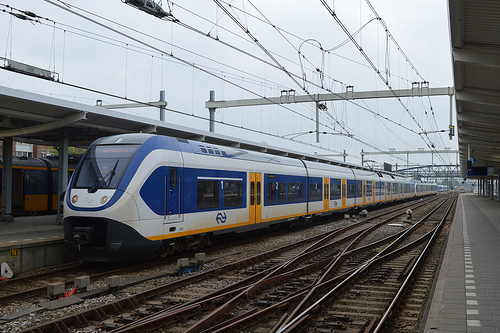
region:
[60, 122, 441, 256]
a long colorful train partked on the track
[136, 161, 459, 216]
the blue strip on the train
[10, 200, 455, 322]
the empty tracks next to the train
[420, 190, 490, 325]
the platform next to othe enpty track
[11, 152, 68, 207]
another colorful train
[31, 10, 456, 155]
assorted electrical equipment above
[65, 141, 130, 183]
the front window of the train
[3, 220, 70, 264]
another section of the platform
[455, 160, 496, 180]
a sign above the platform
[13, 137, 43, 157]
a building off in the background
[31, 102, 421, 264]
A train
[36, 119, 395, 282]
A blue, white and yellow train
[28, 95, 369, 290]
A train at a station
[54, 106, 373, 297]
A train on tracks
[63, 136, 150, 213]
The windshield of a train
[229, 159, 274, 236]
The doors of a train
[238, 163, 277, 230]
The yellow doors of a train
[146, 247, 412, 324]
train tracks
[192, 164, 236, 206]
A white number "1"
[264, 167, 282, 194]
A white number "2"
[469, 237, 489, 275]
part of a walkpath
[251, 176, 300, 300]
edge of a rail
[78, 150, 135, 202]
part of a window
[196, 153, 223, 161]
part of the upper edge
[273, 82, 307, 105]
part of a metal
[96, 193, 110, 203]
part of aheadlight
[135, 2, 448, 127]
A lot of wires above.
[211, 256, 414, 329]
Train tracks.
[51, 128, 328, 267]
The train is yellow, white and blue.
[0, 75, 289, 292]
The train is in station.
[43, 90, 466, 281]
The train has many cars.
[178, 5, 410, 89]
The skies are overcast.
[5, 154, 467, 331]
There are three sets of tracks.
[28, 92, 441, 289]
The train is stopped.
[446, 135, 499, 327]
The station is empty.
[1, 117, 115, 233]
Another train can be seen as well.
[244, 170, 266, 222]
yellow doors on the train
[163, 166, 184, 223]
a blue door on the train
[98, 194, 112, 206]
a head light on the train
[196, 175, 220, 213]
a window on the train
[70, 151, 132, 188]
a windshield on the train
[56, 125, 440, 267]
a white, blue, and yellow train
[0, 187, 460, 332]
sets of train tracks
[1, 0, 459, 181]
a gray sky overhead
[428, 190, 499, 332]
a gray sidewalk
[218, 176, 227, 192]
a white number on the train